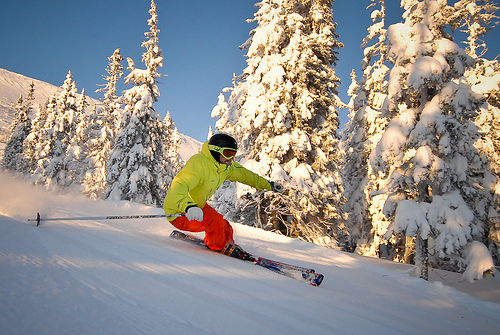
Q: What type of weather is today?
A: It is clear.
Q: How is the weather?
A: It is clear.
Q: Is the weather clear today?
A: Yes, it is clear.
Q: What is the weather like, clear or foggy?
A: It is clear.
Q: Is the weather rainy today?
A: No, it is clear.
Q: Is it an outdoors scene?
A: Yes, it is outdoors.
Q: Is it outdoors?
A: Yes, it is outdoors.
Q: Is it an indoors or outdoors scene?
A: It is outdoors.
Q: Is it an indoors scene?
A: No, it is outdoors.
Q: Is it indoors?
A: No, it is outdoors.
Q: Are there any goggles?
A: Yes, there are goggles.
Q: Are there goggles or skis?
A: Yes, there are goggles.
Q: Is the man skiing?
A: Yes, the man is skiing.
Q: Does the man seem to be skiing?
A: Yes, the man is skiing.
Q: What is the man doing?
A: The man is skiing.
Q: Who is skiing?
A: The man is skiing.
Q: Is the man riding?
A: No, the man is skiing.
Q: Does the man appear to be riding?
A: No, the man is skiing.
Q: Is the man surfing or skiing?
A: The man is skiing.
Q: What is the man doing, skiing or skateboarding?
A: The man is skiing.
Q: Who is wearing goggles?
A: The man is wearing goggles.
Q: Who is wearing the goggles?
A: The man is wearing goggles.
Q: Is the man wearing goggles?
A: Yes, the man is wearing goggles.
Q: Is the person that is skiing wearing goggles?
A: Yes, the man is wearing goggles.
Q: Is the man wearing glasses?
A: No, the man is wearing goggles.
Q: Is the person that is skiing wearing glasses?
A: No, the man is wearing goggles.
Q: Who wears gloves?
A: The man wears gloves.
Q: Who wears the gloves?
A: The man wears gloves.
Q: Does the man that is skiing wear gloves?
A: Yes, the man wears gloves.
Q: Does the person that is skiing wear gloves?
A: Yes, the man wears gloves.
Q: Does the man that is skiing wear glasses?
A: No, the man wears gloves.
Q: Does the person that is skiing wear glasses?
A: No, the man wears gloves.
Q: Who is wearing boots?
A: The man is wearing boots.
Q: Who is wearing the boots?
A: The man is wearing boots.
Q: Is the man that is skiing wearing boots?
A: Yes, the man is wearing boots.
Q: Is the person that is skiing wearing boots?
A: Yes, the man is wearing boots.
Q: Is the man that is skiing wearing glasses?
A: No, the man is wearing boots.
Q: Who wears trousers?
A: The man wears trousers.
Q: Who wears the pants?
A: The man wears trousers.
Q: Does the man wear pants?
A: Yes, the man wears pants.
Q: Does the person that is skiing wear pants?
A: Yes, the man wears pants.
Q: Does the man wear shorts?
A: No, the man wears pants.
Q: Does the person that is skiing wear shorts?
A: No, the man wears pants.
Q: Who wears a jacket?
A: The man wears a jacket.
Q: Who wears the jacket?
A: The man wears a jacket.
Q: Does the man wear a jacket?
A: Yes, the man wears a jacket.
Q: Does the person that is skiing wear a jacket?
A: Yes, the man wears a jacket.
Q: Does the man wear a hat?
A: No, the man wears a jacket.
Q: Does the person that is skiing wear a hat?
A: No, the man wears a jacket.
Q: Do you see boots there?
A: Yes, there are boots.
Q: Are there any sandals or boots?
A: Yes, there are boots.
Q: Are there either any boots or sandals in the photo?
A: Yes, there are boots.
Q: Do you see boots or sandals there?
A: Yes, there are boots.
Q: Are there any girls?
A: No, there are no girls.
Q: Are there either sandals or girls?
A: No, there are no girls or sandals.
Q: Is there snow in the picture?
A: Yes, there is snow.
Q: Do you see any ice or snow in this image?
A: Yes, there is snow.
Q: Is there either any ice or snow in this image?
A: Yes, there is snow.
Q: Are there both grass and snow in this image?
A: No, there is snow but no grass.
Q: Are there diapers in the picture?
A: No, there are no diapers.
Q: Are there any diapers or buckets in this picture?
A: No, there are no diapers or buckets.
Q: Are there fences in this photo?
A: No, there are no fences.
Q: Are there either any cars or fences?
A: No, there are no fences or cars.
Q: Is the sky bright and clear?
A: Yes, the sky is bright and clear.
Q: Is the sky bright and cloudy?
A: No, the sky is bright but clear.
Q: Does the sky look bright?
A: Yes, the sky is bright.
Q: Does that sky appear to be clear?
A: Yes, the sky is clear.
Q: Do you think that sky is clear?
A: Yes, the sky is clear.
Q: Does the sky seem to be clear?
A: Yes, the sky is clear.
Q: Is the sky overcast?
A: No, the sky is clear.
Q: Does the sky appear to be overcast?
A: No, the sky is clear.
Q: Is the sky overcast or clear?
A: The sky is clear.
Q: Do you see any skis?
A: Yes, there are skis.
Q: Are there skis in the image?
A: Yes, there are skis.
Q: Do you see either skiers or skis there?
A: Yes, there are skis.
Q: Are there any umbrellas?
A: No, there are no umbrellas.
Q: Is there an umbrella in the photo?
A: No, there are no umbrellas.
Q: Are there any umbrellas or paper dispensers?
A: No, there are no umbrellas or paper dispensers.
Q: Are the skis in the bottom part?
A: Yes, the skis are in the bottom of the image.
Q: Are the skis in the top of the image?
A: No, the skis are in the bottom of the image.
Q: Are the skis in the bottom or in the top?
A: The skis are in the bottom of the image.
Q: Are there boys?
A: No, there are no boys.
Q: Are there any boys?
A: No, there are no boys.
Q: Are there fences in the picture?
A: No, there are no fences.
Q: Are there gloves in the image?
A: Yes, there are gloves.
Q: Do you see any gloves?
A: Yes, there are gloves.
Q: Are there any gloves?
A: Yes, there are gloves.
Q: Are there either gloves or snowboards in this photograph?
A: Yes, there are gloves.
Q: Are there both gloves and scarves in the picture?
A: No, there are gloves but no scarves.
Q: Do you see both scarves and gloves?
A: No, there are gloves but no scarves.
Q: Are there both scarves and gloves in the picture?
A: No, there are gloves but no scarves.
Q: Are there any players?
A: No, there are no players.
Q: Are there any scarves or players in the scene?
A: No, there are no players or scarves.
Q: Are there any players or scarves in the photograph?
A: No, there are no players or scarves.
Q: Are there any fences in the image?
A: No, there are no fences.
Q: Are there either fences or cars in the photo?
A: No, there are no fences or cars.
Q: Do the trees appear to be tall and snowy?
A: Yes, the trees are tall and snowy.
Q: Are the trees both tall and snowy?
A: Yes, the trees are tall and snowy.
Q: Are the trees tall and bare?
A: No, the trees are tall but snowy.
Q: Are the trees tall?
A: Yes, the trees are tall.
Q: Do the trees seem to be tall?
A: Yes, the trees are tall.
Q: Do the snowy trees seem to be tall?
A: Yes, the trees are tall.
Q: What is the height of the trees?
A: The trees are tall.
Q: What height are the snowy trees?
A: The trees are tall.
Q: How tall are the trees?
A: The trees are tall.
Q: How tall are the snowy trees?
A: The trees are tall.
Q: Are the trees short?
A: No, the trees are tall.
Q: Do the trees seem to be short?
A: No, the trees are tall.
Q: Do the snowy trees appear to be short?
A: No, the trees are tall.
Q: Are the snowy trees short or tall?
A: The trees are tall.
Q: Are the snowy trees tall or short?
A: The trees are tall.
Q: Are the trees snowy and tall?
A: Yes, the trees are snowy and tall.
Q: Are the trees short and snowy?
A: No, the trees are snowy but tall.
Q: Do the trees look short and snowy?
A: No, the trees are snowy but tall.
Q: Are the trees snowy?
A: Yes, the trees are snowy.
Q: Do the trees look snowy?
A: Yes, the trees are snowy.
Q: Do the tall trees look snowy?
A: Yes, the trees are snowy.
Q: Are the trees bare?
A: No, the trees are snowy.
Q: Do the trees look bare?
A: No, the trees are snowy.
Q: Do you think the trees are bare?
A: No, the trees are snowy.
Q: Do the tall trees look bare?
A: No, the trees are snowy.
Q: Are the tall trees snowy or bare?
A: The trees are snowy.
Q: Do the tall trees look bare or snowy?
A: The trees are snowy.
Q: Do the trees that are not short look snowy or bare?
A: The trees are snowy.